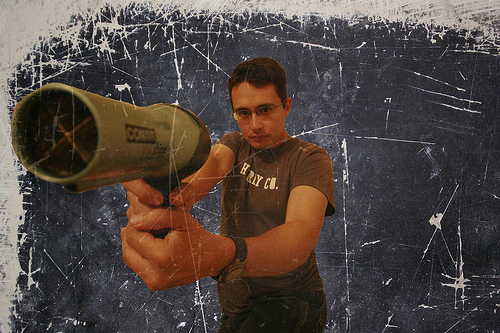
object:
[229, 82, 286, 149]
face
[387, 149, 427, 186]
ground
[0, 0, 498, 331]
black wall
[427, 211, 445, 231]
white marks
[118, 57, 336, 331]
man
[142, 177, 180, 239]
handle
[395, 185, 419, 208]
ground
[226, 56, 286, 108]
brown hair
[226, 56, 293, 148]
head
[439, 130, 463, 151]
ground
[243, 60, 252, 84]
parted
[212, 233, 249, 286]
band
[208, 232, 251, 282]
watch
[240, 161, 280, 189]
logo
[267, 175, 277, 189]
lettering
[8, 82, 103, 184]
nozzle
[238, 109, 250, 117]
eye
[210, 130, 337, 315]
shirt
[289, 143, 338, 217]
sleeve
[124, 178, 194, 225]
hand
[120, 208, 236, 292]
hand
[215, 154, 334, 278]
arm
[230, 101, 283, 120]
eyeglasses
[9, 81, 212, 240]
blow dryer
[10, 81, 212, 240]
something